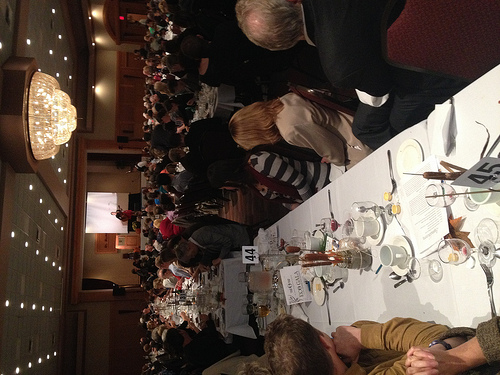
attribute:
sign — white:
[450, 154, 498, 194]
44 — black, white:
[241, 243, 258, 267]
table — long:
[217, 65, 499, 373]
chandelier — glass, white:
[26, 71, 82, 157]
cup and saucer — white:
[378, 237, 415, 279]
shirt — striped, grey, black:
[251, 150, 326, 196]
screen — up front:
[88, 193, 140, 235]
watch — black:
[426, 337, 454, 352]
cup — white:
[352, 211, 378, 238]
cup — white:
[304, 237, 326, 252]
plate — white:
[392, 141, 426, 167]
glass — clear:
[438, 236, 497, 266]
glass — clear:
[410, 261, 444, 282]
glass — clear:
[426, 185, 487, 208]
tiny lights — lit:
[39, 0, 78, 92]